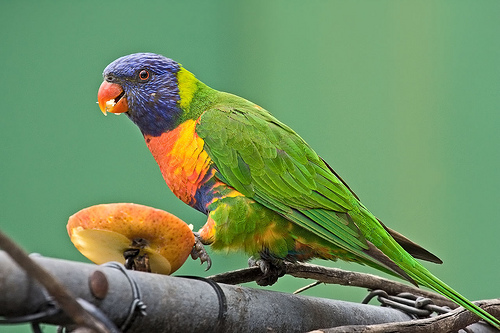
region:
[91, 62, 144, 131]
A bird has an orange beak.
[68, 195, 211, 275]
A birds claw is grasping a potato.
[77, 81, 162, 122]
A bird is eating a potato.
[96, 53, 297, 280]
A parrot is grasping a potato.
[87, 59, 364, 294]
A bird is on a tree branch.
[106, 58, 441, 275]
A tropical bird is on a tree branch.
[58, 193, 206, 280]
A potato is on a tree branch.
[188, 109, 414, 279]
A parrot has green wings.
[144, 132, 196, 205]
a parrot has a red and yellow chest.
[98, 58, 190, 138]
a parrot has a blue face.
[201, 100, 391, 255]
bird's wing is green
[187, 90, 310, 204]
bird's wing is green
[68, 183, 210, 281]
a slice of apple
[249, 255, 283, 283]
The bird foot holding onto the branch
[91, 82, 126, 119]
The bird orange beak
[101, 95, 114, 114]
The peice of food in the birds mouth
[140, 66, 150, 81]
The birds red orange eye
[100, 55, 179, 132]
The birds blue face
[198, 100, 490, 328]
The birds green wing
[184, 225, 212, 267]
The birds foot on the fruit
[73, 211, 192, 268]
The piece of fruit the bird is eating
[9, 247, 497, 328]
The branch the bird is sitting on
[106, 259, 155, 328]
The metal wire on the branch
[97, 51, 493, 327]
a blue yellow and green bird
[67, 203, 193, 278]
a slice of an apple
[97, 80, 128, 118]
beak of a bird holding fruit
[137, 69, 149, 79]
eye of a bird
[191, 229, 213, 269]
a bird has a claw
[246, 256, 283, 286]
a bird has a claw holding onto a branch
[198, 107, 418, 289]
the wing of a bird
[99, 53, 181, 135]
blue head of a bird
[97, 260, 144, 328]
metal wire around a tree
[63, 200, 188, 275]
a slice of fruit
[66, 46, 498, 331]
parrot with blue head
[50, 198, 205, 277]
slice of apple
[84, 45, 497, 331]
bird with blue head and green wings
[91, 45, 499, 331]
colorful bird with many colors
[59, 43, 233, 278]
parrot eating apple slice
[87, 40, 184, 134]
blue face of bird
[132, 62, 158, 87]
eye of a parrot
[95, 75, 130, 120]
beak of a parrot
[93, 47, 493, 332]
parrot with colorful plumage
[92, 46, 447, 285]
small bird standing on perch